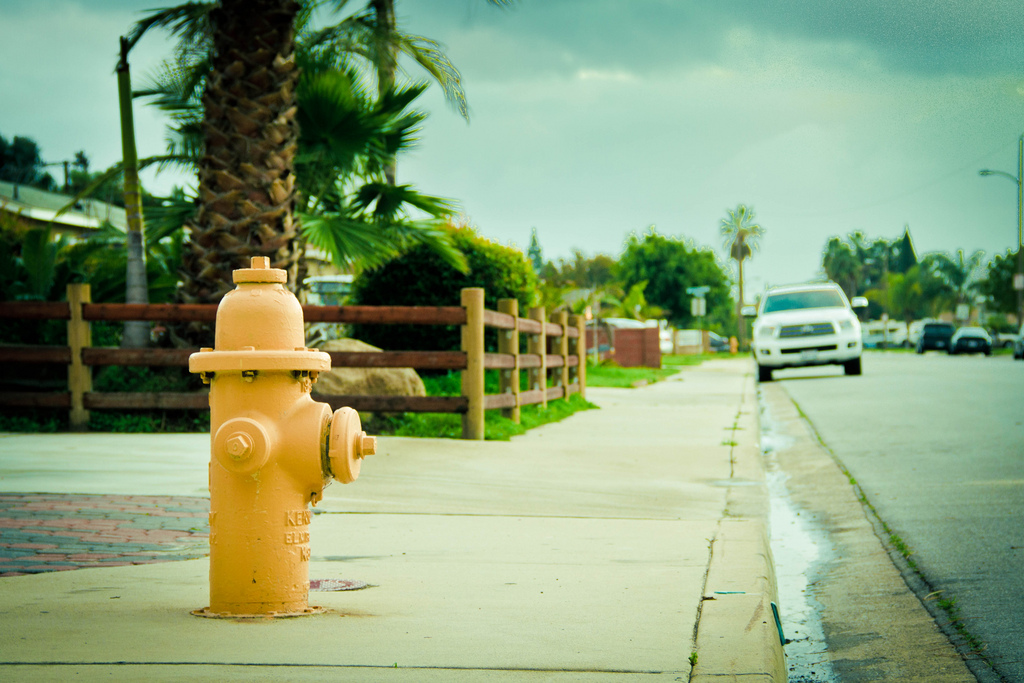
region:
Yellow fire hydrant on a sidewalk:
[190, 252, 377, 617]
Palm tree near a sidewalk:
[112, 3, 466, 425]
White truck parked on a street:
[748, 284, 872, 382]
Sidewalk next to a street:
[4, 350, 969, 674]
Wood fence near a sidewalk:
[5, 277, 582, 432]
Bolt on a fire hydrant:
[223, 430, 247, 462]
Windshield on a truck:
[757, 282, 847, 314]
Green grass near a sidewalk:
[576, 337, 714, 395]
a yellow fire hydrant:
[173, 215, 414, 633]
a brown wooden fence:
[46, 216, 588, 433]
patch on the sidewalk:
[5, 447, 274, 613]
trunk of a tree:
[150, 0, 338, 428]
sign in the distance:
[672, 259, 721, 355]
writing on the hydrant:
[258, 500, 332, 570]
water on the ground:
[716, 364, 846, 668]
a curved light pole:
[953, 136, 1021, 251]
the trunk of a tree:
[190, 22, 296, 304]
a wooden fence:
[66, 296, 589, 423]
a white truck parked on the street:
[755, 287, 854, 373]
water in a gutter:
[759, 470, 836, 674]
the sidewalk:
[381, 418, 726, 679]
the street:
[805, 338, 1011, 560]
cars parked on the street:
[913, 316, 1016, 359]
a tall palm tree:
[713, 206, 753, 308]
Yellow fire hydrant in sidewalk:
[185, 249, 381, 620]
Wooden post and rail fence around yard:
[5, 277, 590, 439]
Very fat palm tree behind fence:
[51, 0, 475, 345]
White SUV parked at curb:
[746, 278, 865, 386]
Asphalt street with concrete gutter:
[774, 351, 1021, 678]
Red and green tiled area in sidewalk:
[2, 489, 209, 578]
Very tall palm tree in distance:
[714, 200, 769, 337]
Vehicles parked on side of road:
[913, 318, 999, 360]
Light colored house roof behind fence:
[0, 180, 130, 237]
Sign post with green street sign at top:
[686, 282, 713, 362]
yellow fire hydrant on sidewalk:
[202, 241, 367, 609]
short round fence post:
[57, 278, 102, 421]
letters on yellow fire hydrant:
[276, 500, 311, 561]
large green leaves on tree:
[304, 201, 419, 266]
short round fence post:
[460, 282, 490, 438]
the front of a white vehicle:
[750, 284, 872, 377]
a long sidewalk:
[2, 339, 765, 668]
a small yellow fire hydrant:
[197, 230, 388, 638]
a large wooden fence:
[5, 263, 597, 442]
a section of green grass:
[580, 354, 658, 387]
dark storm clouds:
[383, 0, 1022, 146]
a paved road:
[791, 313, 1022, 680]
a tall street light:
[965, 160, 1022, 243]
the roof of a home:
[2, 174, 126, 226]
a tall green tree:
[623, 224, 742, 335]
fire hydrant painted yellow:
[185, 250, 381, 627]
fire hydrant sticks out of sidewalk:
[182, 247, 379, 630]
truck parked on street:
[745, 272, 870, 386]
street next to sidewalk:
[761, 335, 1022, 680]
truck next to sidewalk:
[742, 279, 872, 388]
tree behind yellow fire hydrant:
[116, 1, 474, 390]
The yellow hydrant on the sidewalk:
[178, 255, 375, 623]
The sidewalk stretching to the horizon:
[1, 349, 782, 681]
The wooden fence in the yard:
[61, 278, 600, 444]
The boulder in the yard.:
[314, 331, 425, 407]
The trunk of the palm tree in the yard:
[177, 0, 317, 304]